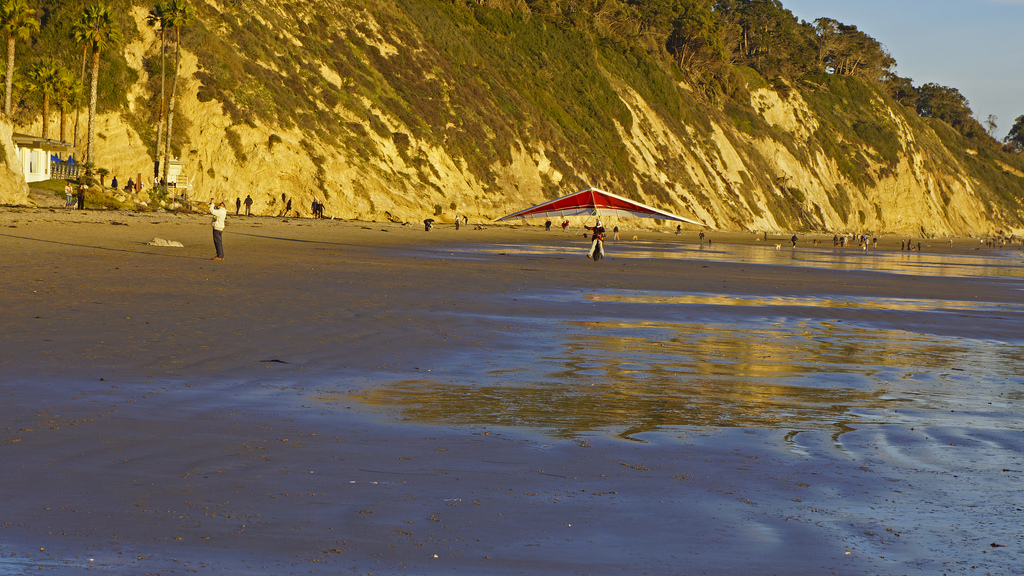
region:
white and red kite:
[476, 183, 704, 228]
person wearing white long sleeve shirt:
[208, 196, 235, 260]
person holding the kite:
[588, 219, 611, 264]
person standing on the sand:
[203, 187, 236, 257]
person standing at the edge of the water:
[576, 210, 618, 264]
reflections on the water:
[378, 292, 967, 451]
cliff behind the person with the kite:
[7, 7, 1020, 248]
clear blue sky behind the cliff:
[802, 16, 1022, 147]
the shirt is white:
[208, 208, 229, 231]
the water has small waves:
[885, 412, 990, 477]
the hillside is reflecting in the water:
[635, 358, 713, 428]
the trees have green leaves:
[751, 13, 802, 53]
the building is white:
[25, 151, 45, 175]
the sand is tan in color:
[76, 225, 115, 258]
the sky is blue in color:
[936, 25, 998, 77]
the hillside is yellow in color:
[265, 159, 301, 194]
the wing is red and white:
[553, 180, 643, 223]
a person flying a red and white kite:
[497, 183, 701, 259]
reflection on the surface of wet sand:
[386, 288, 979, 465]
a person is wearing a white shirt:
[207, 196, 228, 260]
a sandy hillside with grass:
[258, 19, 578, 207]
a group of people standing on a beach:
[700, 231, 907, 251]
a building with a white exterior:
[11, 133, 56, 187]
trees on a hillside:
[507, 0, 894, 90]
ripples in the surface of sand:
[747, 407, 1016, 472]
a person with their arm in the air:
[197, 193, 235, 252]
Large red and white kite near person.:
[503, 179, 694, 234]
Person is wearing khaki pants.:
[584, 239, 604, 258]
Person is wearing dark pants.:
[204, 222, 228, 252]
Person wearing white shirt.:
[199, 203, 232, 235]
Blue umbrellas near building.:
[49, 151, 88, 174]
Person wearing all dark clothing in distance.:
[787, 230, 803, 250]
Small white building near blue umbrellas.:
[8, 116, 63, 173]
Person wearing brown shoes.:
[205, 250, 228, 263]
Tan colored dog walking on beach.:
[767, 241, 791, 257]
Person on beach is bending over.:
[414, 206, 444, 236]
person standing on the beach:
[201, 191, 239, 262]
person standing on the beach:
[226, 185, 237, 212]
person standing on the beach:
[242, 191, 250, 210]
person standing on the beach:
[785, 226, 793, 240]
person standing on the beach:
[585, 220, 606, 256]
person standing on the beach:
[70, 176, 89, 209]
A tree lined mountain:
[6, 14, 1021, 294]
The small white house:
[14, 114, 85, 187]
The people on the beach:
[99, 161, 1016, 275]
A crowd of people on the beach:
[78, 145, 1014, 259]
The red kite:
[511, 174, 702, 235]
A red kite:
[502, 158, 679, 231]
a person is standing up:
[198, 184, 241, 268]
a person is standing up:
[226, 184, 246, 208]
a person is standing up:
[238, 187, 264, 208]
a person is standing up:
[117, 172, 138, 192]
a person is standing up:
[77, 179, 90, 205]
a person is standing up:
[452, 209, 457, 229]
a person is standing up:
[784, 219, 797, 252]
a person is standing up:
[827, 223, 835, 247]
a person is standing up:
[835, 225, 843, 249]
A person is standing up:
[199, 187, 237, 258]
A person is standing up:
[243, 194, 254, 213]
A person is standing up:
[233, 187, 247, 213]